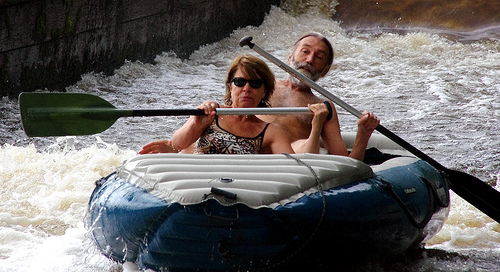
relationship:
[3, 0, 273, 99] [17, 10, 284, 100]
block on wall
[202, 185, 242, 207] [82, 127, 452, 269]
handle on raft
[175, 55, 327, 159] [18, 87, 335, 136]
girl holding oar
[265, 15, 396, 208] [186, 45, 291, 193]
man with woman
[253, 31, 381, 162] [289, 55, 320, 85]
man wearing beard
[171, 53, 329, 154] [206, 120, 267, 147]
girl wearing shirt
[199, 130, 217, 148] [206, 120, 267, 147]
design on shirt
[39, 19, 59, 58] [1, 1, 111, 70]
moss on concrete wall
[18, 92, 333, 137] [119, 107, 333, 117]
oar end of stick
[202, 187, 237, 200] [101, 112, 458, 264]
handle for boat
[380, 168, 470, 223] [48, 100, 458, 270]
handles on boat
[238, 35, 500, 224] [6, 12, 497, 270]
boat stick going into water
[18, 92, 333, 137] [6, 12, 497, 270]
oar going into water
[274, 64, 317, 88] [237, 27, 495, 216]
writing on side of boat stick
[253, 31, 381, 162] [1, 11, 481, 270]
man paddling in waters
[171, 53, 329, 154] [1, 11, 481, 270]
girl paddling in waters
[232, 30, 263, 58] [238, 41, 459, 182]
knob on end of stick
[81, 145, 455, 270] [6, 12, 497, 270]
raft in water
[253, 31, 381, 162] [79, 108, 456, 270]
man in raft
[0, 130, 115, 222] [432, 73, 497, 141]
froth on top of water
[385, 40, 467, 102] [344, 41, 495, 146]
wave in water